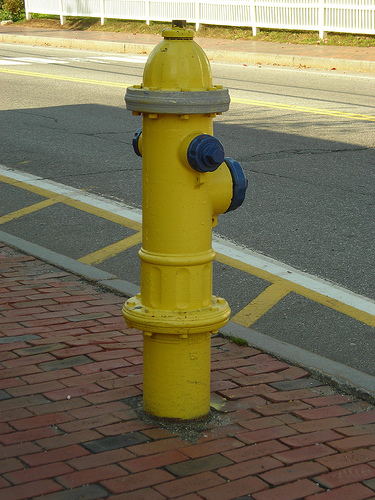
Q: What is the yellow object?
A: Fire hydrant.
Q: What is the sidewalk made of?
A: Red brick.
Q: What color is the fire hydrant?
A: Yellow and blue.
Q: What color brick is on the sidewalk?
A: Red.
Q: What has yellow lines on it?
A: Street.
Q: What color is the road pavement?
A: Gray.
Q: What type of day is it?
A: Sunny.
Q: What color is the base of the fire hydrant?
A: Yellow.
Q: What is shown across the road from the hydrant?
A: Fence.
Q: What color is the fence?
A: White.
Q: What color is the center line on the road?
A: Yellow.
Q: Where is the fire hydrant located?
A: Sidewalk.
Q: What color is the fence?
A: White.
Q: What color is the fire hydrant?
A: Yellow.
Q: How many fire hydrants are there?
A: One.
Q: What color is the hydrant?
A: Yellow.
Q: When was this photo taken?
A: Daytime.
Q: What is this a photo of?
A: A fire hydrant.